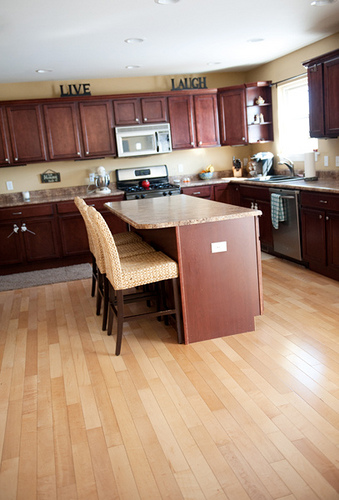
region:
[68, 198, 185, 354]
four legged cushioned wooden chair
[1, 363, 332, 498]
the wooden tiles of a kitchen area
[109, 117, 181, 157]
a microwave on top shelf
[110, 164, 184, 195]
a kitchen gas stove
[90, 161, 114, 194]
a blender on a kitchen top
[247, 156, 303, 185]
a faucet and sink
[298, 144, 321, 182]
a roll of paper towels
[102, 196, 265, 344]
kitchen eating counter top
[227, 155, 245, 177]
a set of knives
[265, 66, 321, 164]
a bright window behind the sink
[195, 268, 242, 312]
black wood surface of the cabinet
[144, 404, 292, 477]
tan wood surface of the floor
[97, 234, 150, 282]
white cloth seats of the chairs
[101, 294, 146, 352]
brown wood legs of the chair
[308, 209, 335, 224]
grey knobs on the cabinet doors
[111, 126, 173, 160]
grey microwave over the counter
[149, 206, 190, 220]
tan granite surface of the counter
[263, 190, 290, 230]
green and white towl hanging on the dishwasher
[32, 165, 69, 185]
a sign hanging on the wall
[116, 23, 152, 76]
white recessed lights in the ceiling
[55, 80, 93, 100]
Wooden piece of art that says live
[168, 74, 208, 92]
Wooden piece of art that says laugh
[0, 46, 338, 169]
Dark brown cabinets hung on the wall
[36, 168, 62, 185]
Small wooden sign hanging on the wall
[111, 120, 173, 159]
White built in microwave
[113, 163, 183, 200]
Stainless steel and black range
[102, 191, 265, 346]
Brown kitchen island with granite countertop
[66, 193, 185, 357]
Three chairs next to the island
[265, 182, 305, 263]
Stainless stell dishwasher under the counter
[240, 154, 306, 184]
Stainless steel kitchen sink and faucet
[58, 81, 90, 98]
"live" sign on the cabinet top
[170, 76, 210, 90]
"laugh" sign on the cabinet top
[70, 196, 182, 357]
chairs pushed under the island bar in the kitchen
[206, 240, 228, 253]
outlet on the island bar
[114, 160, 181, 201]
stainless steel oven in the kitchen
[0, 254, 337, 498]
hardwood flooring on the ground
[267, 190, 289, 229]
blue and white striped towel on a handle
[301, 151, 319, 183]
paper towels on a rod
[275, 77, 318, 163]
bright open window above the sink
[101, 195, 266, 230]
marble counter top on the island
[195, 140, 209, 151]
knob on the cabinet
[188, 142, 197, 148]
knob on the cabinet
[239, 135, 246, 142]
knob on the cabinet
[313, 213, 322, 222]
knob on the cabinet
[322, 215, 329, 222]
knob on the cabinet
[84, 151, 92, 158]
knob on the cabinet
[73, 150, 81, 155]
knob on the cabinet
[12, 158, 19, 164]
knob on the cabinet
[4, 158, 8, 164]
knob on the cabinet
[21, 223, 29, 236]
knob on the cabinet